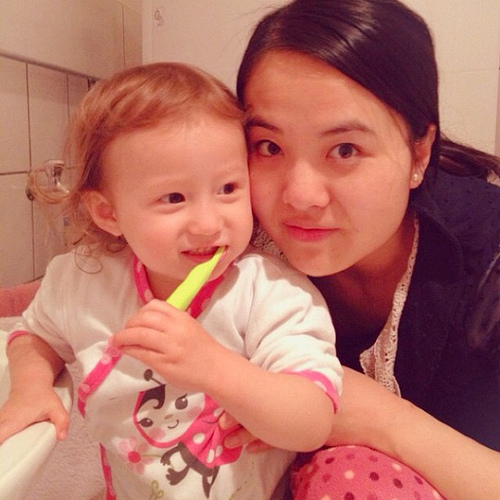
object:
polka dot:
[343, 470, 355, 480]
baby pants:
[288, 441, 442, 499]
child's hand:
[111, 298, 222, 392]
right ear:
[82, 188, 123, 237]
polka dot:
[368, 455, 378, 462]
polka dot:
[325, 455, 335, 464]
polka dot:
[415, 475, 424, 484]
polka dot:
[346, 452, 354, 459]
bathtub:
[0, 335, 74, 500]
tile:
[67, 73, 89, 168]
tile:
[26, 64, 70, 171]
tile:
[0, 57, 30, 174]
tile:
[33, 169, 71, 280]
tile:
[0, 172, 34, 288]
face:
[119, 118, 253, 282]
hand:
[0, 380, 70, 446]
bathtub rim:
[0, 328, 76, 500]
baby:
[0, 64, 342, 500]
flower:
[116, 434, 155, 475]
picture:
[127, 359, 251, 493]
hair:
[239, 0, 443, 276]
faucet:
[30, 161, 70, 226]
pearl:
[413, 172, 420, 182]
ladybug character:
[132, 367, 242, 496]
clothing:
[2, 242, 343, 498]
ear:
[409, 124, 438, 189]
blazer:
[393, 170, 500, 453]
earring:
[412, 172, 420, 182]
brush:
[166, 247, 226, 313]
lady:
[237, 1, 500, 500]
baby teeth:
[197, 248, 210, 253]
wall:
[6, 1, 142, 285]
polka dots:
[390, 461, 403, 472]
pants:
[288, 443, 442, 500]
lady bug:
[134, 368, 253, 497]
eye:
[218, 182, 239, 196]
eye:
[155, 191, 186, 207]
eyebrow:
[213, 164, 247, 180]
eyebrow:
[135, 178, 183, 190]